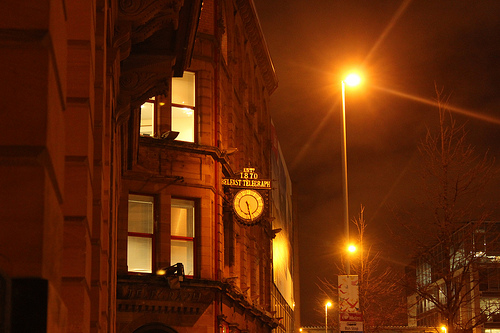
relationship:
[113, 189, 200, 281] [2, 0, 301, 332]
window on building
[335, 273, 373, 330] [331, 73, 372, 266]
sign on lamp post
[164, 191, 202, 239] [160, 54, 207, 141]
light in window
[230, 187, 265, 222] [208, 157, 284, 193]
clock on sign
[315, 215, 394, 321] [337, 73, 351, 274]
bare tree next to lamp post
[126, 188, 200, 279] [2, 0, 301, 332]
window on building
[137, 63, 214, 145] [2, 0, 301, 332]
window on building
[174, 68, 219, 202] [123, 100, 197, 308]
lights showing through window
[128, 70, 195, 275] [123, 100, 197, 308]
window lights showing through window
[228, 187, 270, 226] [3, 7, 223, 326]
clock attached to building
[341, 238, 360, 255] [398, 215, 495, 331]
lights are in building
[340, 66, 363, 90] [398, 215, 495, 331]
lights are in building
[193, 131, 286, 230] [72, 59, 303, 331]
clock face on side of building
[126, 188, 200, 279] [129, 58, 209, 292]
window on side of building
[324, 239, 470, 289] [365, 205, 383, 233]
tree branches with no leaves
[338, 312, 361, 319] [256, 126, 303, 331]
writing on side of building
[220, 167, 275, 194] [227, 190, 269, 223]
sign with clock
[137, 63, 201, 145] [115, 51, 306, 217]
window on second story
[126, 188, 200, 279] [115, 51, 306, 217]
window on second story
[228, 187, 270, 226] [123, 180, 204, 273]
clock next to window